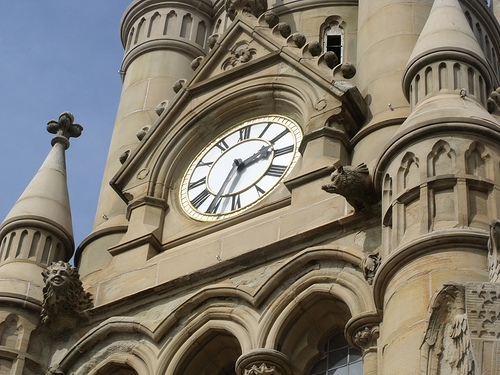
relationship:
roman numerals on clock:
[188, 122, 294, 213] [179, 114, 303, 223]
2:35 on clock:
[186, 123, 297, 216] [179, 114, 303, 223]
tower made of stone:
[0, 0, 499, 374] [0, 1, 499, 374]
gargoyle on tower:
[322, 162, 376, 212] [0, 0, 499, 374]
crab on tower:
[220, 40, 256, 71] [0, 0, 499, 374]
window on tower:
[325, 35, 341, 63] [0, 0, 499, 374]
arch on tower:
[255, 245, 380, 374] [0, 0, 499, 374]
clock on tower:
[179, 114, 303, 223] [0, 0, 499, 374]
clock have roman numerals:
[179, 114, 303, 223] [188, 122, 294, 213]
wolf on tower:
[322, 161, 379, 212] [0, 0, 499, 374]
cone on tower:
[1, 142, 76, 263] [0, 0, 499, 374]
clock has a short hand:
[179, 114, 303, 223] [234, 143, 274, 169]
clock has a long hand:
[179, 114, 303, 223] [205, 159, 241, 214]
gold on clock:
[179, 112, 303, 223] [179, 114, 303, 223]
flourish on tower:
[353, 326, 379, 350] [0, 0, 499, 374]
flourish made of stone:
[353, 326, 379, 350] [0, 1, 499, 374]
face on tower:
[47, 265, 70, 289] [0, 0, 499, 374]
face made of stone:
[47, 265, 70, 289] [0, 1, 499, 374]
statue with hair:
[39, 260, 92, 330] [39, 260, 95, 326]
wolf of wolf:
[322, 161, 379, 215] [322, 161, 379, 212]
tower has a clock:
[0, 0, 499, 374] [179, 114, 303, 223]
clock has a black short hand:
[179, 114, 303, 223] [234, 143, 274, 169]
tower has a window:
[0, 0, 499, 374] [325, 35, 341, 63]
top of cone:
[46, 111, 83, 149] [1, 142, 76, 263]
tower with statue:
[0, 0, 499, 374] [39, 260, 92, 335]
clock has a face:
[179, 114, 303, 223] [179, 116, 304, 220]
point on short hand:
[268, 141, 276, 150] [234, 143, 274, 169]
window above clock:
[325, 35, 341, 63] [179, 114, 303, 223]